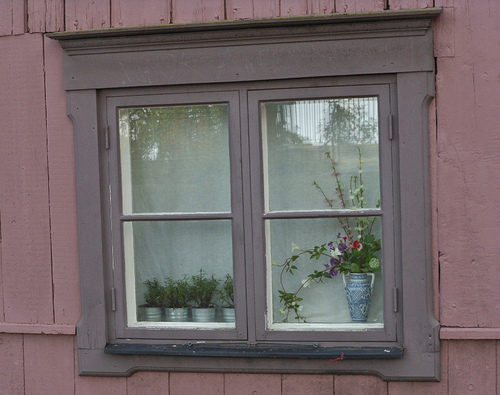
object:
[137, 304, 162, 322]
buckets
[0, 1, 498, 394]
house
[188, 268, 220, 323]
plants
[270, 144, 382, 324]
plant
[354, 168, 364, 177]
flowers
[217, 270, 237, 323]
plants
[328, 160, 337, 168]
flower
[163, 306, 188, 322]
can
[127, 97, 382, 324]
curtain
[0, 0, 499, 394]
wood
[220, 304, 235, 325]
metal can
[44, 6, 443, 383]
window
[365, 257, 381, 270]
flower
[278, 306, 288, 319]
flower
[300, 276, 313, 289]
flower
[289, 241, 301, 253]
flower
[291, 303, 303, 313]
flower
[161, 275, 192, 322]
plants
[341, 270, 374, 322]
vase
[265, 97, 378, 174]
reflection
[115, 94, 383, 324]
glass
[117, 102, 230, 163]
tree reflected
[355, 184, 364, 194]
flowers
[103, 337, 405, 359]
window sill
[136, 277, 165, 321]
plants